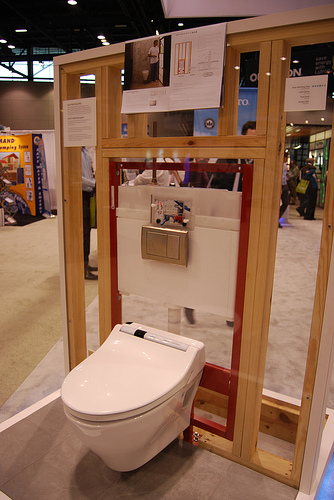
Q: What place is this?
A: It is a display.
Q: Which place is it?
A: It is a display.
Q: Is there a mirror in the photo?
A: No, there are no mirrors.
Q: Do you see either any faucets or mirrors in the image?
A: No, there are no mirrors or faucets.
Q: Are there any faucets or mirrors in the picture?
A: No, there are no mirrors or faucets.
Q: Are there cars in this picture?
A: No, there are no cars.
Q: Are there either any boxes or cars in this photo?
A: No, there are no cars or boxes.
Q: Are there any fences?
A: No, there are no fences.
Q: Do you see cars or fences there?
A: No, there are no fences or cars.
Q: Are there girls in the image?
A: No, there are no girls.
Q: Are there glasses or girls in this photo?
A: No, there are no girls or glasses.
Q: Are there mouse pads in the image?
A: No, there are no mouse pads.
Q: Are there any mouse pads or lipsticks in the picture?
A: No, there are no mouse pads or lipsticks.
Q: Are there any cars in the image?
A: No, there are no cars.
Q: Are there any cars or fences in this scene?
A: No, there are no cars or fences.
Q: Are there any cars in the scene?
A: No, there are no cars.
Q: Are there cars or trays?
A: No, there are no cars or trays.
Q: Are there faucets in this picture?
A: No, there are no faucets.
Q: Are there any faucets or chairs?
A: No, there are no faucets or chairs.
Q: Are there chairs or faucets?
A: No, there are no faucets or chairs.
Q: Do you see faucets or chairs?
A: No, there are no faucets or chairs.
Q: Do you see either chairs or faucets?
A: No, there are no faucets or chairs.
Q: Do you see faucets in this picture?
A: No, there are no faucets.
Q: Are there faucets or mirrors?
A: No, there are no faucets or mirrors.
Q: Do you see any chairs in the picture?
A: No, there are no chairs.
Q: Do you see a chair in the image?
A: No, there are no chairs.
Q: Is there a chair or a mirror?
A: No, there are no chairs or mirrors.